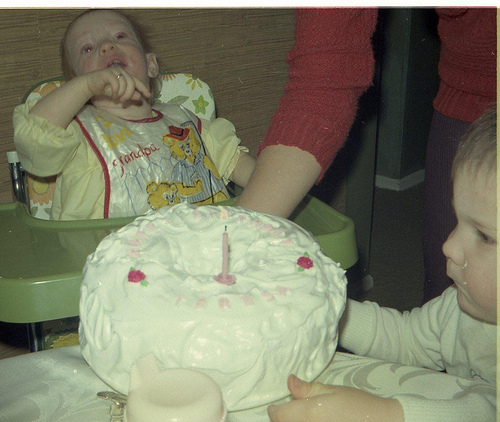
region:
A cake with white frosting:
[77, 202, 353, 411]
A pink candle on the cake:
[213, 223, 239, 285]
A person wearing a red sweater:
[251, 9, 498, 186]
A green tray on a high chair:
[0, 191, 360, 326]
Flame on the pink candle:
[219, 204, 229, 224]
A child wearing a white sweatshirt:
[335, 281, 497, 420]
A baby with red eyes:
[81, 30, 130, 57]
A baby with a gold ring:
[114, 70, 125, 81]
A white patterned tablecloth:
[0, 340, 498, 420]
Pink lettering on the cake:
[126, 208, 298, 310]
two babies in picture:
[51, 29, 483, 388]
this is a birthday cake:
[51, 155, 394, 392]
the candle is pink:
[181, 215, 293, 360]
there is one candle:
[163, 187, 262, 317]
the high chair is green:
[20, 23, 345, 319]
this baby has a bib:
[26, 34, 241, 201]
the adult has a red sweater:
[103, 23, 419, 253]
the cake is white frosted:
[71, 187, 357, 330]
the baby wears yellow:
[25, 20, 262, 225]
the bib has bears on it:
[82, 49, 241, 236]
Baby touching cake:
[72, 198, 357, 413]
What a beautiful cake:
[73, 197, 355, 412]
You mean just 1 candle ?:
[71, 200, 359, 414]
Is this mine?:
[70, 196, 360, 414]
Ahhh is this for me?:
[71, 195, 358, 408]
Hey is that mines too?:
[11, 3, 355, 416]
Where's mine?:
[13, 5, 358, 415]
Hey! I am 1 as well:
[16, 7, 354, 416]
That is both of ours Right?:
[16, 9, 362, 414]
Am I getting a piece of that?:
[11, 8, 355, 413]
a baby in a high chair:
[24, 11, 377, 289]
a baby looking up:
[9, 18, 339, 279]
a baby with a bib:
[19, 21, 326, 328]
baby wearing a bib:
[14, 23, 408, 338]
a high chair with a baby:
[14, 23, 364, 356]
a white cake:
[32, 158, 485, 420]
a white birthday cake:
[85, 189, 374, 401]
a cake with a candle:
[32, 203, 349, 403]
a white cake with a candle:
[53, 183, 353, 418]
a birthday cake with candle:
[30, 151, 378, 419]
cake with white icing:
[65, 186, 345, 396]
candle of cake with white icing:
[216, 222, 238, 286]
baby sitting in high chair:
[25, 24, 237, 214]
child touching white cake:
[265, 109, 494, 419]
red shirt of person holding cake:
[262, 11, 478, 176]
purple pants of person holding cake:
[425, 116, 470, 288]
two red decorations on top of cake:
[122, 246, 314, 288]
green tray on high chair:
[5, 183, 350, 333]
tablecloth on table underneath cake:
[5, 344, 498, 411]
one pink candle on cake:
[216, 224, 233, 284]